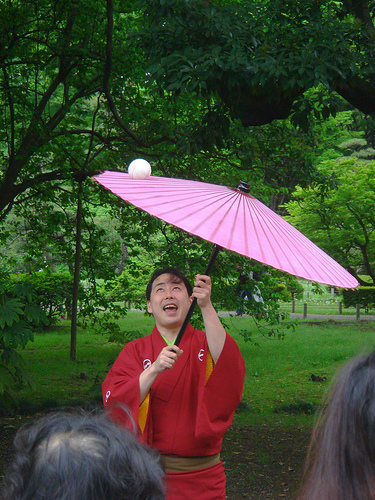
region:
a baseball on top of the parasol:
[129, 159, 149, 178]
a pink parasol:
[94, 170, 356, 355]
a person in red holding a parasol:
[93, 170, 357, 487]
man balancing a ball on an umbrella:
[85, 157, 358, 486]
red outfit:
[100, 324, 246, 499]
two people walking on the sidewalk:
[234, 266, 264, 317]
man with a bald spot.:
[13, 417, 160, 497]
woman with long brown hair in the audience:
[298, 348, 370, 498]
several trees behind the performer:
[2, 2, 371, 350]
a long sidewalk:
[105, 302, 372, 323]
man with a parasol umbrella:
[81, 140, 358, 493]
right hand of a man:
[154, 337, 195, 390]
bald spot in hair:
[41, 424, 96, 457]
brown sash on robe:
[153, 447, 230, 474]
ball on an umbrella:
[123, 143, 165, 184]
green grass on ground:
[257, 330, 319, 407]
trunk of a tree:
[63, 171, 98, 367]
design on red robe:
[193, 340, 210, 372]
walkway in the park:
[298, 302, 371, 328]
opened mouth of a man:
[161, 299, 182, 320]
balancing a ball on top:
[111, 157, 289, 243]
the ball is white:
[130, 149, 153, 175]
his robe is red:
[126, 337, 239, 440]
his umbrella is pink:
[126, 187, 330, 247]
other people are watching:
[14, 321, 374, 498]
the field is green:
[18, 286, 348, 441]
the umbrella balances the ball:
[92, 146, 168, 201]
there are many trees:
[116, 80, 348, 270]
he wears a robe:
[57, 333, 244, 434]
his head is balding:
[40, 414, 135, 480]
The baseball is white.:
[129, 156, 150, 177]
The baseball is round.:
[126, 157, 149, 181]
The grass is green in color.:
[261, 347, 307, 383]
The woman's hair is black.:
[9, 417, 165, 498]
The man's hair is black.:
[137, 265, 202, 329]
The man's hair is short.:
[143, 267, 195, 323]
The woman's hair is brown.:
[294, 344, 371, 499]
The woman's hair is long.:
[304, 359, 373, 499]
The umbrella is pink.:
[96, 158, 357, 336]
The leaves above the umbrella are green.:
[212, 128, 291, 165]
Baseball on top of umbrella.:
[125, 155, 156, 183]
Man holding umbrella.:
[92, 164, 372, 365]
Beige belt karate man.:
[158, 448, 231, 477]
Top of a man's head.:
[6, 406, 161, 498]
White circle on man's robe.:
[103, 384, 114, 404]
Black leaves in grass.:
[310, 368, 326, 385]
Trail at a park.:
[292, 303, 370, 322]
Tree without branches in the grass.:
[70, 173, 79, 358]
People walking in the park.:
[231, 258, 276, 321]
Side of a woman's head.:
[305, 350, 364, 489]